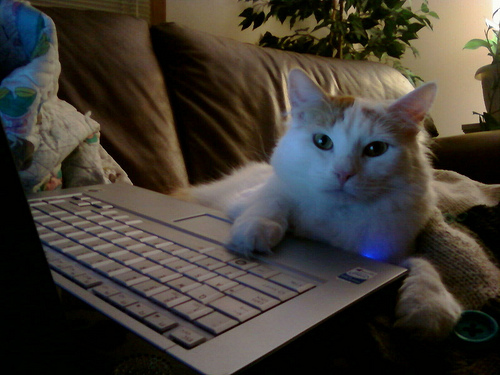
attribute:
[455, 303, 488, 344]
button — green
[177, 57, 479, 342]
cat — white and orange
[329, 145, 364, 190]
nose — pink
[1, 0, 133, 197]
blanket — child's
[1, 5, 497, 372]
couch — brown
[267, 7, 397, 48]
leaves — green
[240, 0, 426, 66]
plant — green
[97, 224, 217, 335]
keys — silver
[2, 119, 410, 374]
computer — laptop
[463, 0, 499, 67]
plant — green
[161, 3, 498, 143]
wall — white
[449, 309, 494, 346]
soda lid — green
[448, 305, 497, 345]
button — green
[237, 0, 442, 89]
tree — fake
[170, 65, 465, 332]
cat — looking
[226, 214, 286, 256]
paw — white